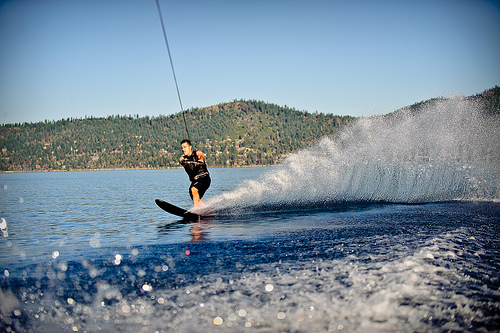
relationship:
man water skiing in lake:
[175, 139, 212, 210] [5, 176, 432, 247]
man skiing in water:
[177, 135, 212, 205] [3, 0, 490, 324]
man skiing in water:
[175, 139, 212, 210] [0, 165, 499, 331]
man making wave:
[175, 139, 212, 210] [229, 204, 356, 215]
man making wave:
[175, 139, 212, 210] [399, 193, 499, 205]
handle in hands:
[179, 153, 199, 165] [179, 157, 207, 165]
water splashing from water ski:
[198, 94, 498, 212] [151, 191, 252, 224]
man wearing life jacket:
[175, 139, 212, 210] [176, 149, 209, 181]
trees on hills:
[5, 130, 305, 151] [2, 80, 497, 171]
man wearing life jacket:
[175, 139, 212, 210] [181, 152, 209, 174]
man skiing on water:
[175, 139, 212, 210] [5, 175, 493, 331]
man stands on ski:
[175, 139, 212, 210] [154, 197, 226, 220]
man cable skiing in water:
[175, 139, 212, 210] [0, 165, 499, 331]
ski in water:
[154, 192, 190, 218] [108, 205, 499, 330]